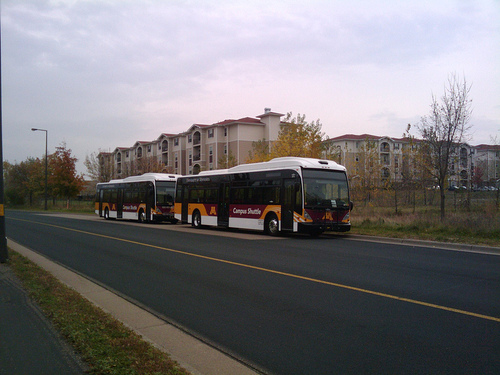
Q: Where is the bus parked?
A: Side of road.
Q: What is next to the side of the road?
A: Two buses.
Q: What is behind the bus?
A: Apartment building.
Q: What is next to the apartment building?
A: Another apartment building.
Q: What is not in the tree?
A: Leaves.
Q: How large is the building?
A: Three floors.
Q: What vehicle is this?
A: A bus.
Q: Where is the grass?
A: On the side of the road.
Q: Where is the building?
A: Behind the bus.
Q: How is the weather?
A: Over cast.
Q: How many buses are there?
A: Two.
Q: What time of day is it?
A: Morning.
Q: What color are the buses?
A: Yellow and white.